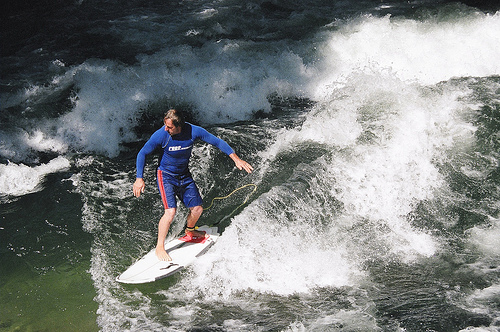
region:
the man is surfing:
[56, 82, 312, 302]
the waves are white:
[248, 110, 450, 310]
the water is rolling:
[72, 25, 317, 183]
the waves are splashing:
[257, 161, 474, 319]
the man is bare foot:
[138, 212, 222, 274]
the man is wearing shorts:
[116, 155, 225, 220]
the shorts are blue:
[129, 158, 224, 224]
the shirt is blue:
[117, 102, 235, 174]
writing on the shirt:
[155, 135, 203, 165]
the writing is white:
[156, 139, 201, 162]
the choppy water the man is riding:
[4, 1, 498, 330]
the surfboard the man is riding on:
[116, 219, 212, 289]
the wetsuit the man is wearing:
[128, 120, 237, 208]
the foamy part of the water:
[68, 33, 494, 108]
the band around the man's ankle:
[182, 220, 199, 232]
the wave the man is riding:
[78, 126, 448, 264]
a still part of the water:
[6, 189, 96, 329]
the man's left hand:
[230, 154, 248, 179]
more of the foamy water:
[344, 53, 427, 210]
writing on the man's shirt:
[166, 140, 188, 156]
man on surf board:
[116, 105, 242, 299]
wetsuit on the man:
[137, 132, 212, 214]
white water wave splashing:
[275, 256, 294, 273]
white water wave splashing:
[343, 273, 364, 293]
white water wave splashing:
[209, 290, 225, 307]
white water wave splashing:
[408, 185, 433, 207]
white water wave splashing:
[315, 171, 335, 190]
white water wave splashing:
[176, 305, 194, 328]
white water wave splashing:
[271, 200, 297, 223]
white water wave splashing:
[331, 133, 348, 151]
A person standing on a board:
[112, 86, 247, 312]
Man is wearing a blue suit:
[133, 100, 260, 270]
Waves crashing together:
[298, 19, 498, 221]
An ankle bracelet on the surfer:
[186, 223, 206, 245]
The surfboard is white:
[111, 215, 225, 286]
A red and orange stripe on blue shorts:
[154, 163, 169, 209]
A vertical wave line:
[69, 158, 119, 330]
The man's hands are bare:
[230, 150, 255, 174]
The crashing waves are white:
[366, 30, 496, 73]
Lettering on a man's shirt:
[163, 138, 197, 155]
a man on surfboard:
[111, 105, 229, 295]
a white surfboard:
[124, 262, 151, 288]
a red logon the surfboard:
[174, 229, 209, 245]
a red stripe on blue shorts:
[151, 168, 172, 205]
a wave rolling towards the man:
[166, 16, 482, 96]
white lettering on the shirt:
[165, 137, 182, 152]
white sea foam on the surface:
[351, 174, 399, 212]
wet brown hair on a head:
[169, 111, 178, 119]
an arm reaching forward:
[201, 129, 254, 170]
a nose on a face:
[160, 125, 181, 134]